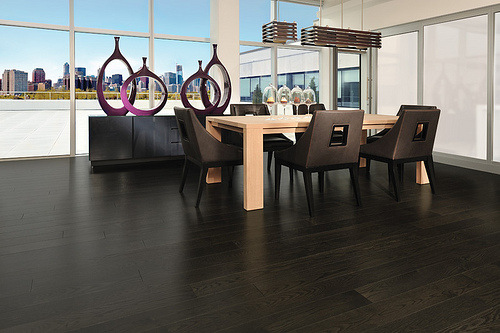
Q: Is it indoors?
A: Yes, it is indoors.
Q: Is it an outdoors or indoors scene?
A: It is indoors.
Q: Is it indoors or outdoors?
A: It is indoors.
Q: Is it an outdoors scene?
A: No, it is indoors.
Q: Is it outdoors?
A: No, it is indoors.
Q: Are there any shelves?
A: No, there are no shelves.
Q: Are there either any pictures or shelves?
A: No, there are no shelves or pictures.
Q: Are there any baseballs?
A: No, there are no baseballs.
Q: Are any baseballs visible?
A: No, there are no baseballs.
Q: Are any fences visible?
A: No, there are no fences.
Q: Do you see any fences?
A: No, there are no fences.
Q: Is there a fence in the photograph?
A: No, there are no fences.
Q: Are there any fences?
A: No, there are no fences.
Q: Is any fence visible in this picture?
A: No, there are no fences.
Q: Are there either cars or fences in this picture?
A: No, there are no fences or cars.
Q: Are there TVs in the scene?
A: No, there are no tvs.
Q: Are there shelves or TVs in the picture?
A: No, there are no TVs or shelves.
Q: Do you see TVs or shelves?
A: No, there are no TVs or shelves.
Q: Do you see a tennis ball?
A: No, there are no tennis balls.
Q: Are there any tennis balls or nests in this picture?
A: No, there are no tennis balls or nests.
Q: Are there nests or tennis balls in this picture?
A: No, there are no tennis balls or nests.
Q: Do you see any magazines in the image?
A: No, there are no magazines.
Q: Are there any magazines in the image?
A: No, there are no magazines.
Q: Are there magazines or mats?
A: No, there are no magazines or mats.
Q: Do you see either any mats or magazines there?
A: No, there are no magazines or mats.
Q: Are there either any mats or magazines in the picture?
A: No, there are no magazines or mats.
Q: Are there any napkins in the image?
A: No, there are no napkins.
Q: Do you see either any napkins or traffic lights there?
A: No, there are no napkins or traffic lights.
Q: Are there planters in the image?
A: No, there are no planters.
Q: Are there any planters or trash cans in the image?
A: No, there are no planters or trash cans.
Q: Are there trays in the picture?
A: No, there are no trays.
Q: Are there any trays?
A: No, there are no trays.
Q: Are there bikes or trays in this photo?
A: No, there are no trays or bikes.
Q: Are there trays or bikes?
A: No, there are no trays or bikes.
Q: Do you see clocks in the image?
A: No, there are no clocks.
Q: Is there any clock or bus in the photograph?
A: No, there are no clocks or buses.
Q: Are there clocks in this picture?
A: No, there are no clocks.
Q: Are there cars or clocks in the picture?
A: No, there are no clocks or cars.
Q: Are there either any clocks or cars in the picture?
A: No, there are no clocks or cars.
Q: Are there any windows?
A: Yes, there is a window.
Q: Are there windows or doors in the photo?
A: Yes, there is a window.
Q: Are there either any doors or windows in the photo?
A: Yes, there is a window.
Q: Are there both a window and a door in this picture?
A: No, there is a window but no doors.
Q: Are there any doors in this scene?
A: No, there are no doors.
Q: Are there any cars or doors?
A: No, there are no doors or cars.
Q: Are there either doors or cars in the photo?
A: No, there are no doors or cars.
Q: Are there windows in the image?
A: Yes, there is a window.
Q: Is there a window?
A: Yes, there is a window.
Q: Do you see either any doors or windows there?
A: Yes, there is a window.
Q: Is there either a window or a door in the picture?
A: Yes, there is a window.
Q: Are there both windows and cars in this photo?
A: No, there is a window but no cars.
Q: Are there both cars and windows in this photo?
A: No, there is a window but no cars.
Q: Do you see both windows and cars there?
A: No, there is a window but no cars.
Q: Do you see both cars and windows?
A: No, there is a window but no cars.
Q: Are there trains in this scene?
A: No, there are no trains.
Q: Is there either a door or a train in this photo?
A: No, there are no trains or doors.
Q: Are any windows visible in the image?
A: Yes, there is a window.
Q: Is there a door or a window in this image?
A: Yes, there is a window.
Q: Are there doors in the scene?
A: No, there are no doors.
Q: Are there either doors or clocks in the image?
A: No, there are no doors or clocks.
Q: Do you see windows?
A: Yes, there is a window.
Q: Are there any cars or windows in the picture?
A: Yes, there is a window.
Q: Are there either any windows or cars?
A: Yes, there is a window.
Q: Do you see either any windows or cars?
A: Yes, there is a window.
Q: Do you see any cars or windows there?
A: Yes, there is a window.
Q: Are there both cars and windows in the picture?
A: No, there is a window but no cars.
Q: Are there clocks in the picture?
A: No, there are no clocks.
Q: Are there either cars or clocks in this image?
A: No, there are no clocks or cars.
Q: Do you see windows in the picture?
A: Yes, there is a window.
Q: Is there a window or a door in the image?
A: Yes, there is a window.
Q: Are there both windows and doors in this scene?
A: No, there is a window but no doors.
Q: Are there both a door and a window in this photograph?
A: No, there is a window but no doors.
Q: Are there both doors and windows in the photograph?
A: No, there is a window but no doors.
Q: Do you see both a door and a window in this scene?
A: No, there is a window but no doors.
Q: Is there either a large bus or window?
A: Yes, there is a large window.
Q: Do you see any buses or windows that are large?
A: Yes, the window is large.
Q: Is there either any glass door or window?
A: Yes, there is a glass window.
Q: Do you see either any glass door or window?
A: Yes, there is a glass window.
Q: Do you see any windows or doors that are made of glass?
A: Yes, the window is made of glass.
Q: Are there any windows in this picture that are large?
A: Yes, there is a large window.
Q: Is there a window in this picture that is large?
A: Yes, there is a window that is large.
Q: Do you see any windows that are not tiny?
A: Yes, there is a large window.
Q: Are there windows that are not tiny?
A: Yes, there is a large window.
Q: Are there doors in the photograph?
A: No, there are no doors.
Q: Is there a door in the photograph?
A: No, there are no doors.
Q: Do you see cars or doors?
A: No, there are no doors or cars.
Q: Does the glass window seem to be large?
A: Yes, the window is large.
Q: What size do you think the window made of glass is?
A: The window is large.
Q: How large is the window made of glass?
A: The window is large.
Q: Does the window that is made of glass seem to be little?
A: No, the window is large.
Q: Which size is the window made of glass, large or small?
A: The window is large.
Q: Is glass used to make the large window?
A: Yes, the window is made of glass.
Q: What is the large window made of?
A: The window is made of glass.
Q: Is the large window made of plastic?
A: No, the window is made of glass.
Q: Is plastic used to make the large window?
A: No, the window is made of glass.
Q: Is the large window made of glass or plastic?
A: The window is made of glass.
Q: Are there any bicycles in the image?
A: No, there are no bicycles.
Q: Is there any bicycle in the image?
A: No, there are no bicycles.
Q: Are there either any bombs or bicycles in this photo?
A: No, there are no bicycles or bombs.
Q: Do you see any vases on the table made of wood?
A: Yes, there is a vase on the table.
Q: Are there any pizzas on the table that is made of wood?
A: No, there is a vase on the table.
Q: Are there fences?
A: No, there are no fences.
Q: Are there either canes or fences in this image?
A: No, there are no fences or canes.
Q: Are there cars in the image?
A: No, there are no cars.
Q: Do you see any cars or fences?
A: No, there are no cars or fences.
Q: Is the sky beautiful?
A: Yes, the sky is beautiful.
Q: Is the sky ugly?
A: No, the sky is beautiful.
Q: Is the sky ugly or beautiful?
A: The sky is beautiful.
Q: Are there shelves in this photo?
A: No, there are no shelves.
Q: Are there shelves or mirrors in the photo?
A: No, there are no shelves or mirrors.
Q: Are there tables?
A: Yes, there is a table.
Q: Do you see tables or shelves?
A: Yes, there is a table.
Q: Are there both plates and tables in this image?
A: No, there is a table but no plates.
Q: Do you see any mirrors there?
A: No, there are no mirrors.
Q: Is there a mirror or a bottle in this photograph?
A: No, there are no mirrors or bottles.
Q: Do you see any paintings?
A: No, there are no paintings.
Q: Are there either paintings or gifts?
A: No, there are no paintings or gifts.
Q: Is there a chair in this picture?
A: Yes, there is a chair.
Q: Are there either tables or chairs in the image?
A: Yes, there is a chair.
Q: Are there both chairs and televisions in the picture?
A: No, there is a chair but no televisions.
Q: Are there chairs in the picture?
A: Yes, there is a chair.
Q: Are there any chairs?
A: Yes, there is a chair.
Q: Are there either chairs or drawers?
A: Yes, there is a chair.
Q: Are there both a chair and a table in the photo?
A: Yes, there are both a chair and a table.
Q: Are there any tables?
A: Yes, there is a table.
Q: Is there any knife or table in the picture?
A: Yes, there is a table.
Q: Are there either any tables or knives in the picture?
A: Yes, there is a table.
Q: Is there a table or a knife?
A: Yes, there is a table.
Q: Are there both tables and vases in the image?
A: Yes, there are both a table and a vase.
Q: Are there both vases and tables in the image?
A: Yes, there are both a table and a vase.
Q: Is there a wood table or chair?
A: Yes, there is a wood table.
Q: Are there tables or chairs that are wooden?
A: Yes, the table is wooden.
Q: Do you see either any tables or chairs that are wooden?
A: Yes, the table is wooden.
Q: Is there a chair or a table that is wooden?
A: Yes, the table is wooden.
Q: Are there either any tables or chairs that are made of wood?
A: Yes, the table is made of wood.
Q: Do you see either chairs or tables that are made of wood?
A: Yes, the table is made of wood.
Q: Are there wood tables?
A: Yes, there is a table that is made of wood.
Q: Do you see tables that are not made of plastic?
A: Yes, there is a table that is made of wood.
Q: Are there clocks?
A: No, there are no clocks.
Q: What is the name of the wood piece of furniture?
A: The piece of furniture is a table.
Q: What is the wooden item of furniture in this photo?
A: The piece of furniture is a table.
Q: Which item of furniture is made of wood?
A: The piece of furniture is a table.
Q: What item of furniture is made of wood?
A: The piece of furniture is a table.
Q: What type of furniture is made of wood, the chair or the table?
A: The table is made of wood.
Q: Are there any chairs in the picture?
A: Yes, there is a chair.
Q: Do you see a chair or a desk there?
A: Yes, there is a chair.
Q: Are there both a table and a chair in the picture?
A: Yes, there are both a chair and a table.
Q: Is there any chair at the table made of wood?
A: Yes, there is a chair at the table.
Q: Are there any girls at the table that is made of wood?
A: No, there is a chair at the table.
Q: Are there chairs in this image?
A: Yes, there is a chair.